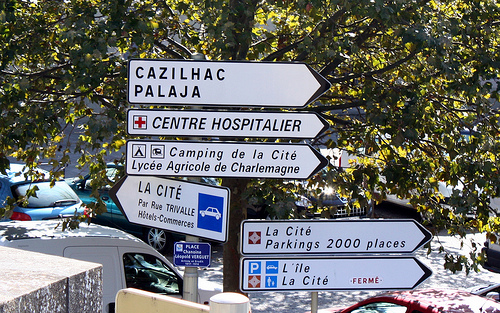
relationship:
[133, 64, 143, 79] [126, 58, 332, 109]
letter on sign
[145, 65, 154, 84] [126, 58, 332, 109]
letter on sign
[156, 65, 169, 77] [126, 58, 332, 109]
letter on sign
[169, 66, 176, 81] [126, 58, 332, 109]
letter on sign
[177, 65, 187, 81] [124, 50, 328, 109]
letter on sign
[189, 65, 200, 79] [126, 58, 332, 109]
letter on sign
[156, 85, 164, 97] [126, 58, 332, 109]
letter on sign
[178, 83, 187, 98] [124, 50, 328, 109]
letter on sign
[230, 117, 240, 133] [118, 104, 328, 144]
letter on sign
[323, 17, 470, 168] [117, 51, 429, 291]
tree behind signs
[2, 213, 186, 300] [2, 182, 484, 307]
van parked in lot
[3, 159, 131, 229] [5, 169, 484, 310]
cars parked in lot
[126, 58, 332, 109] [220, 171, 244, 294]
sign attached to pole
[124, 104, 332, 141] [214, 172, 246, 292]
sign attached to pole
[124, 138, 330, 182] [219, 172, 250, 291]
sign attached to pole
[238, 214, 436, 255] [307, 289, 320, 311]
sign attached to pole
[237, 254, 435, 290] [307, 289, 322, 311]
sign attached to pole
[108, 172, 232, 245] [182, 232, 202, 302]
sign attached to pole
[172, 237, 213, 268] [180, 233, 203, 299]
sign attached to pole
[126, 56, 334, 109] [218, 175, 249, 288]
sign attached to pole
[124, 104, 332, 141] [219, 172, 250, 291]
sign attached to pole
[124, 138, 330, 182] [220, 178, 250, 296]
sign attached to pole